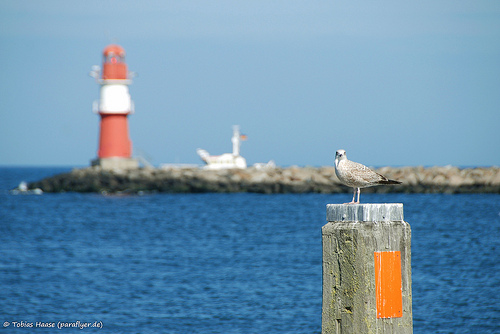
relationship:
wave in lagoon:
[132, 199, 206, 233] [0, 164, 500, 334]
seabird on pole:
[324, 140, 396, 202] [319, 230, 418, 301]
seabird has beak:
[324, 140, 396, 202] [331, 155, 349, 162]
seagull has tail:
[334, 149, 402, 205] [378, 173, 412, 195]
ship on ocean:
[184, 96, 258, 175] [64, 208, 374, 282]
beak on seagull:
[331, 155, 349, 162] [334, 149, 402, 205]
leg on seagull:
[354, 186, 365, 204] [334, 149, 402, 205]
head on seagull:
[326, 143, 354, 162] [334, 149, 402, 205]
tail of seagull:
[378, 173, 412, 195] [334, 149, 402, 205]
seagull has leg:
[334, 149, 402, 205] [354, 186, 365, 204]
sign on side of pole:
[373, 250, 405, 319] [319, 218, 418, 334]